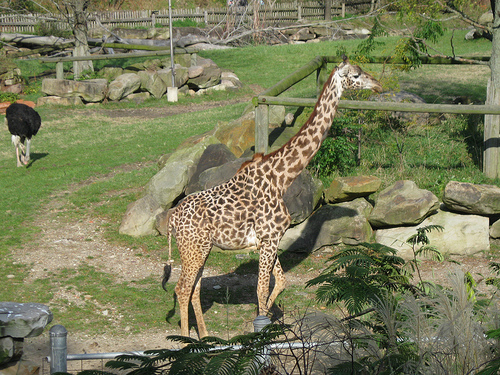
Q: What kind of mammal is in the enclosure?
A: Giraffe.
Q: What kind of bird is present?
A: Ostrich.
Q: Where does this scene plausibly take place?
A: Zoo.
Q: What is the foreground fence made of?
A: Metal.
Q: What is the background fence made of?
A: Wood.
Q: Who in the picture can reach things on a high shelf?
A: Giraffe.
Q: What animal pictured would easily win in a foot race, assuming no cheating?
A: Ostrich.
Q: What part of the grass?
A: Bare.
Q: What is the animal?
A: Giraffe.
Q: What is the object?
A: Rock.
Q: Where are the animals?
A: Zoo.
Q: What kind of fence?
A: Wood.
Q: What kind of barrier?
A: Wooden.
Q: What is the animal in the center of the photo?
A: Giraffe.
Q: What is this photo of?
A: A Giraffe.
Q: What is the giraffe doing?
A: Standing in the grass.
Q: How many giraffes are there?
A: One.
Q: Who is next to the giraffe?
A: Noone.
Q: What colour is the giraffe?
A: Brown and White.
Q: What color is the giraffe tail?
A: Black.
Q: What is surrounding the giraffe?
A: Rocks and Trees.